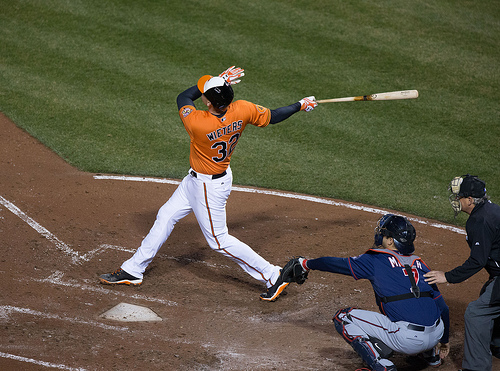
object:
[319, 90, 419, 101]
bat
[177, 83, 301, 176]
shirt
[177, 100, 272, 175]
jersey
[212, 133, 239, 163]
32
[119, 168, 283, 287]
pants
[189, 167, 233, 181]
belt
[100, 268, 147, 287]
shoes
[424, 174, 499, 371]
umpire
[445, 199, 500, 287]
shirt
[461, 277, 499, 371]
pants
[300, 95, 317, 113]
hand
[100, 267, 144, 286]
foot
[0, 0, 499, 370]
ground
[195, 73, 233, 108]
hat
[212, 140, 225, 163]
3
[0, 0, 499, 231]
grass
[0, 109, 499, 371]
ball field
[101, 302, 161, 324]
home base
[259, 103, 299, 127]
arms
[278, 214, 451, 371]
catcher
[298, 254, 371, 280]
arm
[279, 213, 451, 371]
player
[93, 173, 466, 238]
line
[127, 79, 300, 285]
uniform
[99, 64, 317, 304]
ballplayer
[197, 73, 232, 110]
cap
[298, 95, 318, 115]
gloves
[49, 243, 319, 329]
batters box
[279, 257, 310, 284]
mitt